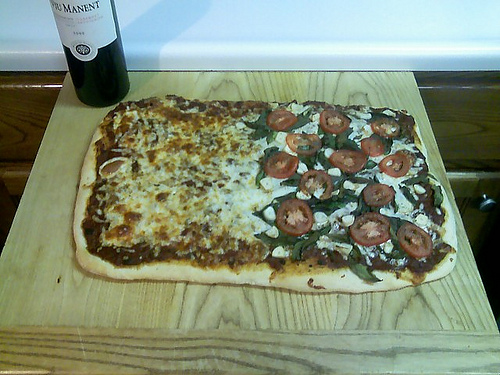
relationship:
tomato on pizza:
[396, 220, 435, 260] [75, 96, 450, 288]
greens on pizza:
[347, 246, 381, 283] [75, 96, 450, 288]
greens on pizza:
[430, 182, 445, 209] [75, 96, 450, 288]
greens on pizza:
[389, 215, 404, 258] [75, 96, 450, 288]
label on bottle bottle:
[50, 0, 117, 60] [50, 0, 132, 108]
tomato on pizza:
[260, 150, 295, 178] [71, 95, 481, 297]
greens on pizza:
[339, 236, 369, 278] [71, 95, 481, 297]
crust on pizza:
[72, 115, 92, 271] [75, 96, 450, 288]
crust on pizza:
[72, 156, 91, 231] [75, 96, 450, 288]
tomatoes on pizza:
[358, 184, 430, 253] [75, 96, 450, 288]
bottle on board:
[50, 0, 130, 107] [4, 58, 490, 338]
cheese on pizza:
[110, 104, 436, 267] [80, 90, 456, 310]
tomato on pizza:
[362, 181, 397, 206] [75, 96, 450, 288]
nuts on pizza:
[262, 103, 431, 256] [75, 96, 450, 288]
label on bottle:
[50, 0, 118, 62] [50, 0, 132, 108]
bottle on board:
[50, 0, 132, 108] [0, 71, 500, 375]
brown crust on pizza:
[73, 118, 458, 293] [75, 96, 450, 288]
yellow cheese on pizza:
[110, 105, 256, 250] [75, 96, 450, 288]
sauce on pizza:
[83, 201, 113, 259] [71, 95, 481, 297]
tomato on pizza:
[301, 170, 333, 203] [71, 95, 481, 297]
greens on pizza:
[347, 246, 381, 283] [71, 95, 481, 297]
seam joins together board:
[3, 322, 498, 372] [0, 71, 500, 375]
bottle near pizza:
[50, 0, 130, 107] [71, 95, 481, 297]